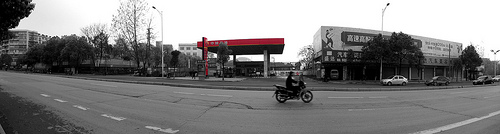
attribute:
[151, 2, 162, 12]
street light — metal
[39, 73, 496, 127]
street — gray, paved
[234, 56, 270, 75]
building — gas station, red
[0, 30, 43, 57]
building — white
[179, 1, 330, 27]
sky — gray